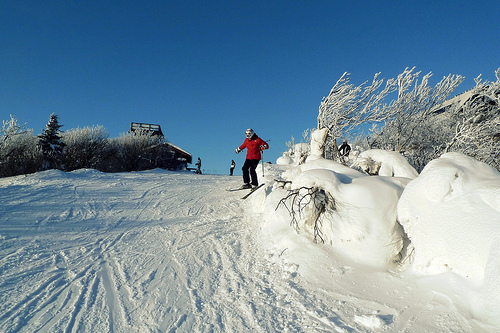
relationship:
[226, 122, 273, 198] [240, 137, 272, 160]
skier has jacket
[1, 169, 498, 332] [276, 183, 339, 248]
snow shows roots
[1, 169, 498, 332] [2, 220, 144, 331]
snow has tracks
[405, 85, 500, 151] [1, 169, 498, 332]
house on snow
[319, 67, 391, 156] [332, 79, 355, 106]
trees have snow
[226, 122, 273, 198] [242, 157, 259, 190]
skier has pants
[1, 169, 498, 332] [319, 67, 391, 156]
snow on trees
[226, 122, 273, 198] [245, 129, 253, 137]
skier has helmet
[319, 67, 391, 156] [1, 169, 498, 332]
trees have snow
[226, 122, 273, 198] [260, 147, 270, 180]
skier has pole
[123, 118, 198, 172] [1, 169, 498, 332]
resort on snow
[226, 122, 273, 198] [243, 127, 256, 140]
skier has head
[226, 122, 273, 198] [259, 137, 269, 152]
skier has arm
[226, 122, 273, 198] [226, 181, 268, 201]
skier has skis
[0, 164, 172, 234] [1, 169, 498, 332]
shadows on snow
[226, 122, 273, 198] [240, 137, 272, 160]
skier wearing red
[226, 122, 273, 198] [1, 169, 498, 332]
skier on snow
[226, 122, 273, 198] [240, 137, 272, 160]
skier has coat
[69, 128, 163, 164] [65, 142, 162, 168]
snow on bush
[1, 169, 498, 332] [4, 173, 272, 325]
snow on ground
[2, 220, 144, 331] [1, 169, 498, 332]
tracks on snow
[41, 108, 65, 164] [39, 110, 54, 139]
tree has snow